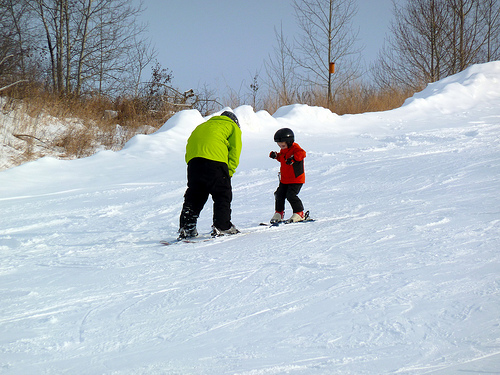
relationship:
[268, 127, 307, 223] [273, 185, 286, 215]
child has leg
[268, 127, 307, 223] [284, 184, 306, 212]
child has leg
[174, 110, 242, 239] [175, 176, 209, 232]
adult has leg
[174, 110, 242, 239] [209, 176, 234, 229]
adult has leg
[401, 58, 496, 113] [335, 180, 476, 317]
pile of snow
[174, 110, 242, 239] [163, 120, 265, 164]
adult wearing jacket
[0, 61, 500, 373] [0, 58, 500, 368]
snow covering hillside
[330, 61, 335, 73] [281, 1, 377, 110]
can in tree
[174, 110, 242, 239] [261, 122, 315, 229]
adult with child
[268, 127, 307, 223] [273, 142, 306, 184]
child wearing jacket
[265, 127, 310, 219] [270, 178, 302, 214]
child wearing pants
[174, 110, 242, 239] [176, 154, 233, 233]
adult wearing pants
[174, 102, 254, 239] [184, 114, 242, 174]
adult wearing jacket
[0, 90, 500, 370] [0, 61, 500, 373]
tracks in snow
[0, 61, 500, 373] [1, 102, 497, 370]
snow on ground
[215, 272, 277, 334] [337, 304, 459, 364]
snow on ground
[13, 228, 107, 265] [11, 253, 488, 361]
snow on ground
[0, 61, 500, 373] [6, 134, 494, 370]
snow on ground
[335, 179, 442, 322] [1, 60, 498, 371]
snow on ground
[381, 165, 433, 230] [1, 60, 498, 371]
snow on ground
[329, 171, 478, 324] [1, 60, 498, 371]
snow on ground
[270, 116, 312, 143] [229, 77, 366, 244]
helmet on child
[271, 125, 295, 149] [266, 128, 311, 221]
head belonging to person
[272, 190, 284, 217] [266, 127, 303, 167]
leg belonging to person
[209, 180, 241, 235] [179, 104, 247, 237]
leg belonging to person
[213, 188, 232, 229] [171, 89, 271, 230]
leg belonging to person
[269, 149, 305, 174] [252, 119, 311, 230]
arm belonging to person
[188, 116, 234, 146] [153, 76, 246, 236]
back belonging to person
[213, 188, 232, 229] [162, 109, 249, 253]
leg belonging to person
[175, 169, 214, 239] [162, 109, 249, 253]
leg belonging to person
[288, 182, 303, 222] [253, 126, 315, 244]
leg belonging to person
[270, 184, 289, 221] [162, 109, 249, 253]
leg belonging to person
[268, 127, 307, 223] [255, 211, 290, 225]
child standing on ski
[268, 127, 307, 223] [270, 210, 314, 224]
child standing on ski